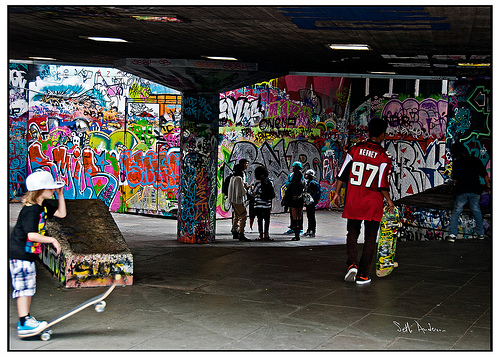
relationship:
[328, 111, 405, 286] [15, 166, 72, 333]
man near boy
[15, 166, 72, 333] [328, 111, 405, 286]
boy near man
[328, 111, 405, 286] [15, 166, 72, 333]
man close to boy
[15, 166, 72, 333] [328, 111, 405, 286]
boy close to man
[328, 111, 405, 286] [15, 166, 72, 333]
man beside boy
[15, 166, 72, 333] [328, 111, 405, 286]
boy beside man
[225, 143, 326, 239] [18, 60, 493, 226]
people near wall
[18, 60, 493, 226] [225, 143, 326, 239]
wall behind people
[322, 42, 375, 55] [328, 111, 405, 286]
light above man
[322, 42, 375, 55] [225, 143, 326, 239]
light above people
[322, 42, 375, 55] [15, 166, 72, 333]
light above boy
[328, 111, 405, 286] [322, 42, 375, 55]
man below light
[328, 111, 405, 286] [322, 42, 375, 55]
man under light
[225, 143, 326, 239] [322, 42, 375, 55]
people under light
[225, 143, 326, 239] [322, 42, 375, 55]
people below light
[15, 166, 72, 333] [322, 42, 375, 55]
boy below light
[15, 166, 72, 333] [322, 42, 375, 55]
boy under light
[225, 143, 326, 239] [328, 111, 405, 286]
people near man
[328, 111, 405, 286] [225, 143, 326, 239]
man near people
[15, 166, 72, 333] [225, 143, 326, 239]
boy near people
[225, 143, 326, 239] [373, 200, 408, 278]
people near board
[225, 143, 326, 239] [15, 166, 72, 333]
people near boy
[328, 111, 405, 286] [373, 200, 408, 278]
man with board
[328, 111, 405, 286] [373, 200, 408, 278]
man has board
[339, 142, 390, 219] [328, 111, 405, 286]
shirt on man